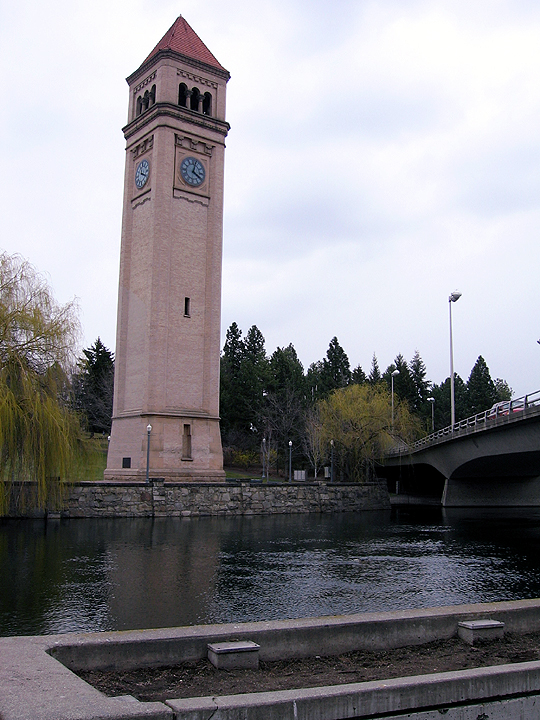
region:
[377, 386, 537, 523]
a bridge over water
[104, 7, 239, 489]
pink tower with a red roof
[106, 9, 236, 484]
a tower on the edge of water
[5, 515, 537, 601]
water running under a bridge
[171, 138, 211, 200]
clock on a tower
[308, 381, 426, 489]
tree next to a bridge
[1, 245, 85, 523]
tree by the water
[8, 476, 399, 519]
rock wall in the water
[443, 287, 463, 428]
light pole on a bridge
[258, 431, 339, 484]
light poles in the grass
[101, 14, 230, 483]
a tall clock tower next to the river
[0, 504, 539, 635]
a river underneath a bridge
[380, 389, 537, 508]
a concrete bridge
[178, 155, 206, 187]
a clock on the face of the tower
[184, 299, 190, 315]
a small window in the middle of the clock tower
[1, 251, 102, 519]
a willow tree next to a clock tower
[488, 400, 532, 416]
a red car driving on top of a bridge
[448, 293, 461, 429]
a silver streetlamp on the bridge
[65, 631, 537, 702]
dirt in a concrete structure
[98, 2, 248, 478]
tall pink and red clock tower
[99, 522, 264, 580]
calm water reflecting tower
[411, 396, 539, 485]
gray bridge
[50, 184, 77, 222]
white clouds in blue sky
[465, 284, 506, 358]
white clouds in blue sky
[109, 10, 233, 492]
pink clock tower with red roof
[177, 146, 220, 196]
clock in pink clock tower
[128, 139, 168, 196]
clock in pink clock tower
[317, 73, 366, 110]
white clouds in blue sky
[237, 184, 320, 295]
white clouds in blue sky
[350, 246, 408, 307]
white clouds in blue sky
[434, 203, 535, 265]
the sky is filled with white clouds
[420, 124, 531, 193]
the sky is filled with white clouds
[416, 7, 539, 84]
the sky is filled with white clouds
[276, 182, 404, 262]
the sky is filled with white clouds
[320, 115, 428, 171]
the sky is filled with white clouds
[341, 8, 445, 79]
the sky is filled with white clouds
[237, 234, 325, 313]
the sky is filled with white clouds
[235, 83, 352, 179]
the sky is filled with white clouds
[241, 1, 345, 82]
the sky is filled with white clouds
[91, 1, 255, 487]
a very tall clock tower